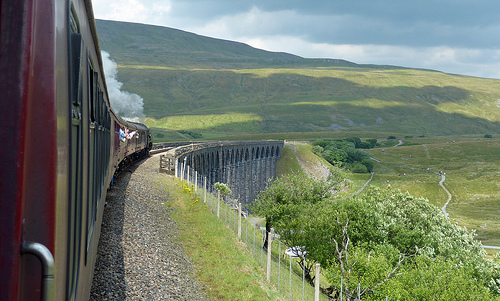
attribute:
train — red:
[20, 0, 156, 281]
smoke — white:
[101, 52, 152, 120]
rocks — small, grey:
[118, 184, 180, 295]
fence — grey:
[183, 159, 326, 288]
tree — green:
[255, 187, 325, 268]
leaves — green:
[277, 191, 292, 208]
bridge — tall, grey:
[185, 130, 286, 209]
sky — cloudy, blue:
[94, 0, 499, 81]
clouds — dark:
[166, 5, 329, 45]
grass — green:
[345, 139, 499, 252]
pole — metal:
[29, 235, 59, 300]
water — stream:
[439, 169, 455, 231]